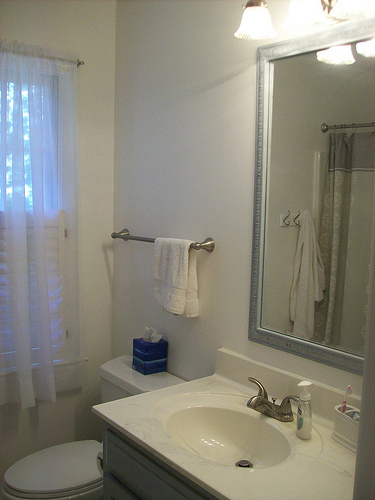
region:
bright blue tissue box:
[128, 317, 177, 383]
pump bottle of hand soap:
[288, 374, 331, 460]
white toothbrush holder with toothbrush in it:
[328, 376, 373, 449]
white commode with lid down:
[2, 419, 117, 498]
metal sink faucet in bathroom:
[239, 369, 306, 430]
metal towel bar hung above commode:
[110, 218, 225, 266]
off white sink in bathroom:
[114, 351, 350, 493]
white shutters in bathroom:
[8, 199, 93, 402]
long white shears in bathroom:
[4, 140, 103, 406]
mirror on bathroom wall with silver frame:
[242, 137, 370, 382]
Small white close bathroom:
[11, 261, 345, 498]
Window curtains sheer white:
[4, 184, 77, 411]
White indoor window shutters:
[2, 206, 77, 368]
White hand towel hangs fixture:
[152, 209, 206, 320]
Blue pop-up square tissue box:
[111, 325, 183, 376]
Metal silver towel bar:
[103, 220, 228, 254]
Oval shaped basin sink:
[174, 359, 340, 498]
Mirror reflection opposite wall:
[254, 92, 373, 364]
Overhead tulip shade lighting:
[236, 0, 373, 35]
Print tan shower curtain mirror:
[311, 116, 373, 335]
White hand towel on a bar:
[144, 232, 221, 317]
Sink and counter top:
[146, 380, 312, 499]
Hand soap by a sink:
[294, 378, 330, 447]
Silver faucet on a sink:
[231, 367, 293, 420]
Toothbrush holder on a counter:
[326, 375, 374, 462]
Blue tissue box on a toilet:
[124, 329, 178, 376]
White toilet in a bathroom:
[6, 332, 180, 494]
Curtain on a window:
[1, 29, 110, 337]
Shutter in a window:
[4, 203, 99, 407]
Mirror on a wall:
[254, 40, 372, 369]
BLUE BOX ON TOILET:
[124, 325, 184, 380]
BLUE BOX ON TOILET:
[106, 316, 169, 382]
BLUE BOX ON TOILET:
[118, 319, 169, 374]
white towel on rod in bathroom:
[110, 226, 214, 318]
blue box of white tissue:
[132, 326, 167, 375]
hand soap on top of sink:
[295, 379, 312, 440]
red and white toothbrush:
[338, 383, 353, 409]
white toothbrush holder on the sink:
[330, 399, 355, 446]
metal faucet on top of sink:
[245, 375, 299, 422]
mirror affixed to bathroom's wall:
[246, 18, 373, 375]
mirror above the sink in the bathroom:
[246, 17, 364, 373]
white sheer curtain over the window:
[0, 38, 86, 410]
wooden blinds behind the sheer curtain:
[0, 210, 70, 369]